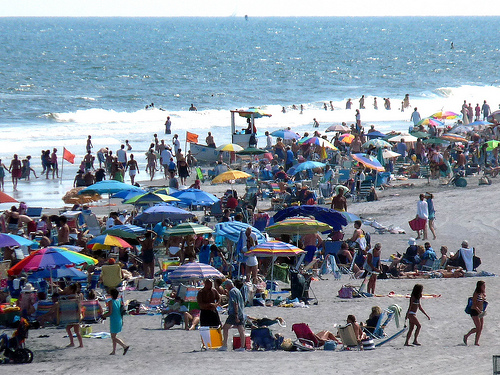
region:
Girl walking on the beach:
[401, 279, 431, 350]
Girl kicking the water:
[23, 152, 40, 181]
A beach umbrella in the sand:
[246, 239, 303, 308]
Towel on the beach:
[376, 288, 441, 300]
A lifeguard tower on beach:
[230, 106, 265, 154]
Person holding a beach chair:
[38, 283, 103, 355]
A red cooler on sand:
[231, 331, 256, 351]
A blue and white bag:
[361, 334, 377, 351]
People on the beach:
[2, 123, 498, 366]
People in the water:
[283, 94, 417, 113]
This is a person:
[405, 278, 440, 360]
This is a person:
[460, 271, 497, 361]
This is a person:
[191, 272, 220, 351]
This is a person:
[105, 275, 141, 364]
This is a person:
[55, 275, 92, 355]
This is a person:
[2, 309, 41, 364]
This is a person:
[244, 225, 268, 285]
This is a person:
[348, 211, 367, 262]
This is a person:
[410, 186, 428, 240]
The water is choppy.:
[83, 35, 239, 92]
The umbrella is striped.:
[164, 258, 227, 284]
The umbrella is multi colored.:
[12, 242, 97, 281]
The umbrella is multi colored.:
[81, 227, 128, 251]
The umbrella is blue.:
[81, 175, 132, 197]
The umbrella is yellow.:
[214, 163, 251, 188]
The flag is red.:
[58, 144, 78, 181]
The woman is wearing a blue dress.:
[99, 290, 145, 359]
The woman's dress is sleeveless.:
[93, 292, 133, 339]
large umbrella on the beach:
[205, 163, 253, 203]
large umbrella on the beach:
[262, 208, 345, 239]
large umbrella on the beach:
[85, 168, 141, 211]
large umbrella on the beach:
[136, 202, 187, 229]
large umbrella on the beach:
[175, 218, 226, 248]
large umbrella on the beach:
[199, 138, 260, 160]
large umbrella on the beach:
[250, 231, 301, 283]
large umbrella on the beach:
[169, 252, 224, 292]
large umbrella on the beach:
[73, 216, 138, 258]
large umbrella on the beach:
[15, 241, 103, 308]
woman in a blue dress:
[104, 288, 134, 363]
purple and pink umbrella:
[168, 258, 223, 285]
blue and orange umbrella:
[240, 233, 302, 258]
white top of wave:
[53, 84, 492, 129]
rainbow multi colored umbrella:
[9, 242, 92, 275]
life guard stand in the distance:
[226, 105, 258, 148]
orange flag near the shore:
[60, 142, 73, 178]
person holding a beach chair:
[467, 278, 484, 345]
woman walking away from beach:
[401, 280, 428, 347]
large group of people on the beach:
[3, 87, 495, 352]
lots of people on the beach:
[62, 161, 314, 304]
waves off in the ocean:
[47, 90, 482, 144]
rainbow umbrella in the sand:
[242, 230, 309, 289]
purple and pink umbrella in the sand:
[170, 257, 241, 308]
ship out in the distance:
[218, 8, 262, 28]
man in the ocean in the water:
[442, 38, 464, 55]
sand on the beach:
[425, 331, 463, 364]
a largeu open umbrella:
[14, 247, 101, 314]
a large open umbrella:
[161, 257, 228, 306]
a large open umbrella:
[246, 237, 301, 306]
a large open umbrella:
[273, 215, 328, 257]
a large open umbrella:
[166, 218, 214, 256]